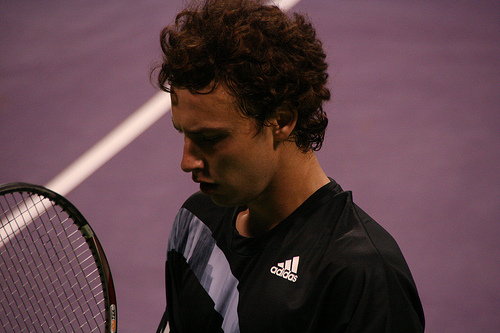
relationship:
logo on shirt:
[272, 256, 302, 281] [167, 180, 426, 331]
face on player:
[171, 80, 269, 206] [157, 0, 424, 332]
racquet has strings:
[3, 180, 116, 332] [2, 191, 105, 331]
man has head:
[157, 0, 424, 332] [154, 3, 329, 210]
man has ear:
[157, 0, 424, 332] [275, 98, 299, 139]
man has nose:
[157, 0, 424, 332] [178, 137, 206, 173]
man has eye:
[157, 0, 424, 332] [200, 135, 214, 144]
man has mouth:
[157, 0, 424, 332] [191, 174, 217, 192]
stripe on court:
[0, 0, 302, 247] [2, 0, 499, 332]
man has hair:
[157, 0, 424, 332] [154, 2, 328, 153]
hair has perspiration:
[154, 2, 328, 153] [149, 3, 328, 153]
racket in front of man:
[3, 180, 116, 332] [157, 0, 424, 332]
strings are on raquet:
[2, 191, 105, 331] [3, 180, 116, 332]